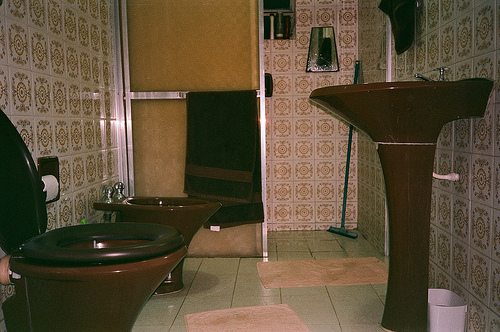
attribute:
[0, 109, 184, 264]
toilet seat — black, uncovered, green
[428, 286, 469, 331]
trash can — white, little, plastic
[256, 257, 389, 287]
bath mat — pink, peach colored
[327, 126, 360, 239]
broom — green, dirty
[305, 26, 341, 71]
mirror — trapezoid shaped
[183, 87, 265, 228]
towel — brown, black, bath towel, hanging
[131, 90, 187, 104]
rack — metal, towel rack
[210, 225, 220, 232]
tag — white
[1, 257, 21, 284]
pipe — silver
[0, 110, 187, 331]
toilet — brown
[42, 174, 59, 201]
toilet paper — small, a roll, white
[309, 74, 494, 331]
sink — brown, dirty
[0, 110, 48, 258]
lid — up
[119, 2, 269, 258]
door — glass, frosted, shower door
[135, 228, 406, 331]
floor — tile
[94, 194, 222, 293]
bidet — brown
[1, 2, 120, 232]
wall — tiled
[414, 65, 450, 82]
tap — silver